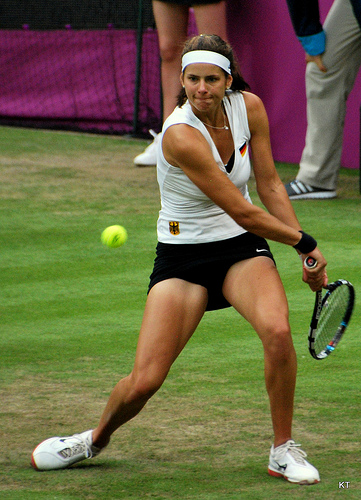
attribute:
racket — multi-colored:
[309, 260, 355, 364]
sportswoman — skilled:
[123, 51, 316, 358]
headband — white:
[163, 46, 257, 81]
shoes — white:
[28, 417, 329, 491]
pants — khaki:
[314, 86, 333, 144]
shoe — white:
[269, 440, 320, 483]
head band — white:
[181, 49, 232, 76]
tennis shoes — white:
[266, 442, 323, 484]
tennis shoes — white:
[30, 426, 111, 469]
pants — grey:
[291, 0, 359, 185]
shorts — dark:
[147, 228, 266, 295]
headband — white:
[166, 40, 240, 74]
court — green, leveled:
[1, 125, 360, 498]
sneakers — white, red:
[27, 430, 323, 485]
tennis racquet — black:
[301, 250, 356, 363]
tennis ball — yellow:
[100, 224, 128, 246]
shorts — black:
[144, 230, 300, 323]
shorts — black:
[142, 236, 294, 325]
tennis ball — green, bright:
[93, 221, 131, 253]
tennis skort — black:
[145, 228, 278, 316]